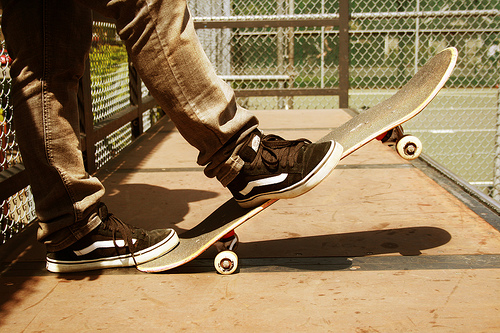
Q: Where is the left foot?
A: On the skateboard.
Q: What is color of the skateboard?
A: White.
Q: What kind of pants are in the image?
A: Jeans.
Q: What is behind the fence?
A: A tennis court.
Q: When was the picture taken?
A: During the daytime.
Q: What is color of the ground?
A: Tab.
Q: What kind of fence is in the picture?
A: Chain link.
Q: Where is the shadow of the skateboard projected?
A: On the ground.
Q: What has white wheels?
A: Skateboard.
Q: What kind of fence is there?
A: Chain link.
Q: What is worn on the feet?
A: Sneakers.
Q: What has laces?
A: Sneakers.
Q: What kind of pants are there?
A: Jeans.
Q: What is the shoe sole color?
A: White.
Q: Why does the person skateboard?
A: Amusement.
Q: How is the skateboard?
A: It is white and grey.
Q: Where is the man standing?
A: On a skate board.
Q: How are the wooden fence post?
A: Brown.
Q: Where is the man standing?
A: On a skateboard platform.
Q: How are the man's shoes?
A: Black and white skate shoes.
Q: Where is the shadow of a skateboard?
A: On the concrete.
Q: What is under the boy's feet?
A: Skateboard.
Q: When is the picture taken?
A: Daytime.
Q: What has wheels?
A: The skateboard.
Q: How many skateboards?
A: One.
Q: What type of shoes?
A: Sneakers.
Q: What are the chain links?
A: Fence.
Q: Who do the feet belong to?
A: A skateboarder.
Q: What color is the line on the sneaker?
A: White.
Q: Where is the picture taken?
A: Skate park.